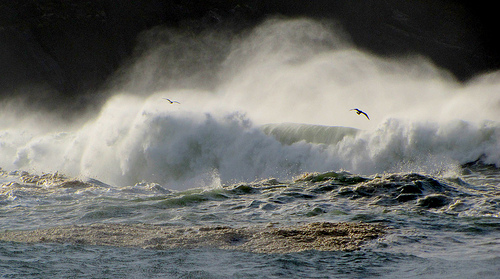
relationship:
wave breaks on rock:
[0, 93, 499, 193] [3, 4, 492, 114]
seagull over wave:
[161, 95, 181, 109] [1, 15, 498, 207]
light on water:
[0, 172, 500, 277] [1, 18, 498, 276]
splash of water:
[90, 79, 467, 208] [204, 96, 323, 183]